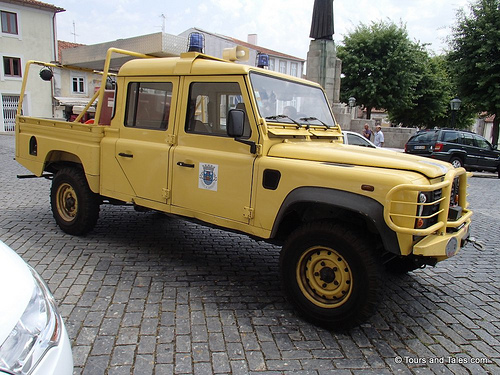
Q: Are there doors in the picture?
A: Yes, there is a door.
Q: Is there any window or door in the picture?
A: Yes, there is a door.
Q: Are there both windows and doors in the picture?
A: Yes, there are both a door and windows.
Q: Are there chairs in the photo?
A: No, there are no chairs.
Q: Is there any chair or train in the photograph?
A: No, there are no chairs or trains.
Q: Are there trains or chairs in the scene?
A: No, there are no chairs or trains.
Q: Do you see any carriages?
A: No, there are no carriages.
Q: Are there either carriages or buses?
A: No, there are no carriages or buses.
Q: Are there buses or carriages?
A: No, there are no carriages or buses.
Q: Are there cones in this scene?
A: No, there are no cones.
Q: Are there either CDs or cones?
A: No, there are no cones or cds.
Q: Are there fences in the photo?
A: No, there are no fences.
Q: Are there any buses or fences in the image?
A: No, there are no fences or buses.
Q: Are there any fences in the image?
A: No, there are no fences.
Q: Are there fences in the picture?
A: No, there are no fences.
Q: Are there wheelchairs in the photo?
A: No, there are no wheelchairs.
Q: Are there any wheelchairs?
A: No, there are no wheelchairs.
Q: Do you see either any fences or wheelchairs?
A: No, there are no wheelchairs or fences.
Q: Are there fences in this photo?
A: No, there are no fences.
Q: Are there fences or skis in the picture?
A: No, there are no fences or skis.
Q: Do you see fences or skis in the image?
A: No, there are no fences or skis.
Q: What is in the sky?
A: The clouds are in the sky.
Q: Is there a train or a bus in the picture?
A: No, there are no trains or buses.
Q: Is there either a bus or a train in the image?
A: No, there are no trains or buses.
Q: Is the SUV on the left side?
A: No, the SUV is on the right of the image.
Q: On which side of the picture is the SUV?
A: The SUV is on the right of the image.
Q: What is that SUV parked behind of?
A: The SUV is parked behind the car.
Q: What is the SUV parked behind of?
A: The SUV is parked behind the car.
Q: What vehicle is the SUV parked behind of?
A: The SUV is parked behind the car.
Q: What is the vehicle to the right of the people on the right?
A: The vehicle is a SUV.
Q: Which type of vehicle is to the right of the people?
A: The vehicle is a SUV.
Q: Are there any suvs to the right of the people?
A: Yes, there is a SUV to the right of the people.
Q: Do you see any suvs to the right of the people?
A: Yes, there is a SUV to the right of the people.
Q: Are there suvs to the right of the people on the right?
A: Yes, there is a SUV to the right of the people.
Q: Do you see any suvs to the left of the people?
A: No, the SUV is to the right of the people.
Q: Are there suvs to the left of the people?
A: No, the SUV is to the right of the people.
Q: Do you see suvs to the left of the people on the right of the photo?
A: No, the SUV is to the right of the people.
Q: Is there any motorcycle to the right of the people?
A: No, there is a SUV to the right of the people.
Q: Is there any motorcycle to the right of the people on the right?
A: No, there is a SUV to the right of the people.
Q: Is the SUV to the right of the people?
A: Yes, the SUV is to the right of the people.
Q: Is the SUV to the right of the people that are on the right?
A: Yes, the SUV is to the right of the people.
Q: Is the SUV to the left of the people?
A: No, the SUV is to the right of the people.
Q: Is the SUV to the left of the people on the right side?
A: No, the SUV is to the right of the people.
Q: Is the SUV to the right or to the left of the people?
A: The SUV is to the right of the people.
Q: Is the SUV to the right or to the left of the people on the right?
A: The SUV is to the right of the people.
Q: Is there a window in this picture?
A: Yes, there is a window.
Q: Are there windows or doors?
A: Yes, there is a window.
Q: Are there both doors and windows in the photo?
A: Yes, there are both a window and a door.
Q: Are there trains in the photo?
A: No, there are no trains.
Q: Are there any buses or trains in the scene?
A: No, there are no trains or buses.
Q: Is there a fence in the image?
A: No, there are no fences.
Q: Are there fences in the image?
A: No, there are no fences.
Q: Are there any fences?
A: No, there are no fences.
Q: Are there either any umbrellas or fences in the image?
A: No, there are no fences or umbrellas.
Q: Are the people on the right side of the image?
A: Yes, the people are on the right of the image.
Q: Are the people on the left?
A: No, the people are on the right of the image.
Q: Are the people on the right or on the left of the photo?
A: The people are on the right of the image.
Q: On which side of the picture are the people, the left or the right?
A: The people are on the right of the image.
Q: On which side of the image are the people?
A: The people are on the right of the image.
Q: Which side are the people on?
A: The people are on the right of the image.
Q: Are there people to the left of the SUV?
A: Yes, there are people to the left of the SUV.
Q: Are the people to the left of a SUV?
A: Yes, the people are to the left of a SUV.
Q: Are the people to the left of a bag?
A: No, the people are to the left of a SUV.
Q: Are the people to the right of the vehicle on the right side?
A: No, the people are to the left of the SUV.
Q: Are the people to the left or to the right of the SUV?
A: The people are to the left of the SUV.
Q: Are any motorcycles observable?
A: No, there are no motorcycles.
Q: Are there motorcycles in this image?
A: No, there are no motorcycles.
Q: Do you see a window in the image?
A: Yes, there is a window.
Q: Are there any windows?
A: Yes, there is a window.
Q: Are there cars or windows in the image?
A: Yes, there is a window.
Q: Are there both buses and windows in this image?
A: No, there is a window but no buses.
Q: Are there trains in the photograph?
A: No, there are no trains.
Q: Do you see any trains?
A: No, there are no trains.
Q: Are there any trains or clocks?
A: No, there are no trains or clocks.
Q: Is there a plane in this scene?
A: No, there are no airplanes.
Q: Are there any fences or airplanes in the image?
A: No, there are no airplanes or fences.